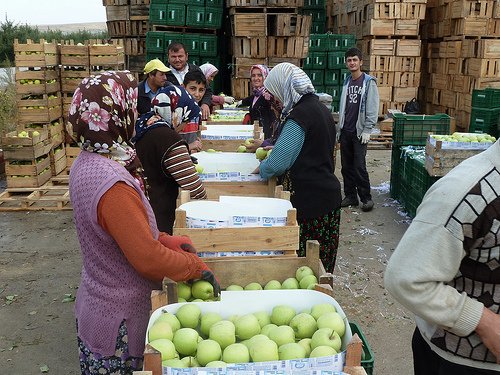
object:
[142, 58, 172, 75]
cap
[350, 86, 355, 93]
white letters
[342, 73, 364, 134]
shirt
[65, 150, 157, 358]
sweater vest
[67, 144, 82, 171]
crate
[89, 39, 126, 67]
crate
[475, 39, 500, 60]
wooden crates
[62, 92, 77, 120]
crate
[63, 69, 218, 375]
woman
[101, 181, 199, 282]
shirt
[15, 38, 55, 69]
wood crate